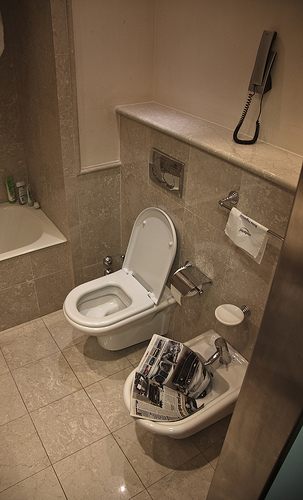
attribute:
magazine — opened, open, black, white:
[128, 333, 211, 422]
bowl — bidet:
[123, 332, 246, 437]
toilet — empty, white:
[62, 206, 178, 350]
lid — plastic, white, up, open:
[118, 205, 176, 303]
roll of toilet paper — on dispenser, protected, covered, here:
[168, 264, 214, 301]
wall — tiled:
[118, 114, 298, 364]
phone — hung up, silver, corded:
[235, 29, 278, 146]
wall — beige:
[72, 3, 302, 168]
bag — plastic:
[222, 206, 270, 264]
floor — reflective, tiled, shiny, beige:
[1, 307, 229, 499]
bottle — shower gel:
[4, 176, 15, 204]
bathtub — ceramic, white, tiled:
[0, 194, 70, 329]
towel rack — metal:
[217, 192, 284, 242]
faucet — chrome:
[200, 337, 230, 368]